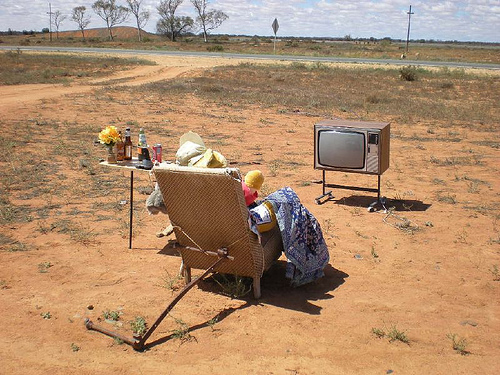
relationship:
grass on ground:
[232, 73, 426, 104] [189, 59, 471, 139]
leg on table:
[118, 170, 138, 255] [93, 152, 170, 177]